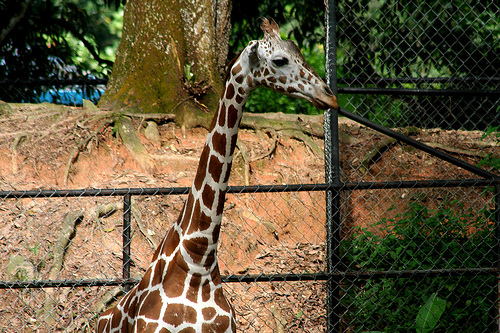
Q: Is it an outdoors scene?
A: Yes, it is outdoors.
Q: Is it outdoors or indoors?
A: It is outdoors.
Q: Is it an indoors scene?
A: No, it is outdoors.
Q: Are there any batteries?
A: No, there are no batteries.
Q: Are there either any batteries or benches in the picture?
A: No, there are no batteries or benches.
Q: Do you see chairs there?
A: No, there are no chairs.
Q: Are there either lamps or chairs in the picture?
A: No, there are no chairs or lamps.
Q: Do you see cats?
A: No, there are no cats.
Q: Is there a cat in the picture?
A: No, there are no cats.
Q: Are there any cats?
A: No, there are no cats.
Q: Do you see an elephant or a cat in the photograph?
A: No, there are no cats or elephants.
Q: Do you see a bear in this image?
A: No, there are no bears.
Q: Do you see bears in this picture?
A: No, there are no bears.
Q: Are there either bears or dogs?
A: No, there are no bears or dogs.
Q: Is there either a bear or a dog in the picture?
A: No, there are no bears or dogs.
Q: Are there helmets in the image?
A: No, there are no helmets.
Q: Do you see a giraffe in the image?
A: Yes, there is a giraffe.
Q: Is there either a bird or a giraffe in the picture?
A: Yes, there is a giraffe.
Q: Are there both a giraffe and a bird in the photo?
A: No, there is a giraffe but no birds.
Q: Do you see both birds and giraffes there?
A: No, there is a giraffe but no birds.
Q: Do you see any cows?
A: No, there are no cows.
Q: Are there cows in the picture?
A: No, there are no cows.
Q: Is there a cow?
A: No, there are no cows.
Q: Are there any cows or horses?
A: No, there are no cows or horses.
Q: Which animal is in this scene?
A: The animal is a giraffe.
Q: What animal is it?
A: The animal is a giraffe.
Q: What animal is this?
A: This is a giraffe.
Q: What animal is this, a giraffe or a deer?
A: This is a giraffe.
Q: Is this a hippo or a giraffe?
A: This is a giraffe.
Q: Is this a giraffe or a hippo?
A: This is a giraffe.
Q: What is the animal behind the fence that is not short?
A: The animal is a giraffe.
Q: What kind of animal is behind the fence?
A: The animal is a giraffe.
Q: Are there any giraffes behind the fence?
A: Yes, there is a giraffe behind the fence.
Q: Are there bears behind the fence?
A: No, there is a giraffe behind the fence.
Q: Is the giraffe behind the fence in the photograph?
A: Yes, the giraffe is behind the fence.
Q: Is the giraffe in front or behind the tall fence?
A: The giraffe is behind the fence.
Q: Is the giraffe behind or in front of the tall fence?
A: The giraffe is behind the fence.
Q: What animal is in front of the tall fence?
A: The giraffe is in front of the fence.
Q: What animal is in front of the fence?
A: The giraffe is in front of the fence.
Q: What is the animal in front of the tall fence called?
A: The animal is a giraffe.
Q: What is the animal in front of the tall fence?
A: The animal is a giraffe.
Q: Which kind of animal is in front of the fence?
A: The animal is a giraffe.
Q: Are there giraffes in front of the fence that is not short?
A: Yes, there is a giraffe in front of the fence.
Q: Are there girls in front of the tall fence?
A: No, there is a giraffe in front of the fence.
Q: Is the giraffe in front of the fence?
A: Yes, the giraffe is in front of the fence.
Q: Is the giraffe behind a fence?
A: No, the giraffe is in front of a fence.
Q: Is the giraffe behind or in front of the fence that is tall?
A: The giraffe is in front of the fence.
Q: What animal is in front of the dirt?
A: The giraffe is in front of the dirt.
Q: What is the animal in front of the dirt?
A: The animal is a giraffe.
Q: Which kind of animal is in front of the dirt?
A: The animal is a giraffe.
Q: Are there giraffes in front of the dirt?
A: Yes, there is a giraffe in front of the dirt.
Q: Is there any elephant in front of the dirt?
A: No, there is a giraffe in front of the dirt.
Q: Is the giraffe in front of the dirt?
A: Yes, the giraffe is in front of the dirt.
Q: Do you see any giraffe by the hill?
A: Yes, there is a giraffe by the hill.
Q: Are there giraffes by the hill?
A: Yes, there is a giraffe by the hill.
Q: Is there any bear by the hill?
A: No, there is a giraffe by the hill.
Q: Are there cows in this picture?
A: No, there are no cows.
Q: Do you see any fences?
A: Yes, there is a fence.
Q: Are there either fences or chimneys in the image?
A: Yes, there is a fence.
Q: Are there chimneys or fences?
A: Yes, there is a fence.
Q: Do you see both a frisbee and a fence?
A: No, there is a fence but no frisbees.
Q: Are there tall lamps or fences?
A: Yes, there is a tall fence.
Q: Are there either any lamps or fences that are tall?
A: Yes, the fence is tall.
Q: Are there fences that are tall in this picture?
A: Yes, there is a tall fence.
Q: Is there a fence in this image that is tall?
A: Yes, there is a fence that is tall.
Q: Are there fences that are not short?
A: Yes, there is a tall fence.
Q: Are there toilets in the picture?
A: No, there are no toilets.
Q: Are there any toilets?
A: No, there are no toilets.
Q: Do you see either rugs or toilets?
A: No, there are no toilets or rugs.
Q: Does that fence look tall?
A: Yes, the fence is tall.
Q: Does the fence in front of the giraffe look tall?
A: Yes, the fence is tall.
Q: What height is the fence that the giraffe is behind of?
A: The fence is tall.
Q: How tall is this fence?
A: The fence is tall.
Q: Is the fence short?
A: No, the fence is tall.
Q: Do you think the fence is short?
A: No, the fence is tall.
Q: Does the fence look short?
A: No, the fence is tall.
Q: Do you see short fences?
A: No, there is a fence but it is tall.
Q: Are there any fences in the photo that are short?
A: No, there is a fence but it is tall.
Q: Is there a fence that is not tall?
A: No, there is a fence but it is tall.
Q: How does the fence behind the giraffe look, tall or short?
A: The fence is tall.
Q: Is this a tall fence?
A: Yes, this is a tall fence.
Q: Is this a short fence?
A: No, this is a tall fence.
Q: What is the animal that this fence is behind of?
A: The animal is a giraffe.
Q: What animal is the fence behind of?
A: The fence is behind the giraffe.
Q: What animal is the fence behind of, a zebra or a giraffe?
A: The fence is behind a giraffe.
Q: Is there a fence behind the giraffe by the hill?
A: Yes, there is a fence behind the giraffe.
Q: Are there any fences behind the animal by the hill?
A: Yes, there is a fence behind the giraffe.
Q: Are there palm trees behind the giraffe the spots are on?
A: No, there is a fence behind the giraffe.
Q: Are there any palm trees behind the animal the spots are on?
A: No, there is a fence behind the giraffe.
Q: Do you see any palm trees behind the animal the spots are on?
A: No, there is a fence behind the giraffe.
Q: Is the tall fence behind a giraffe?
A: Yes, the fence is behind a giraffe.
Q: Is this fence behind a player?
A: No, the fence is behind a giraffe.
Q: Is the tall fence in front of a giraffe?
A: No, the fence is behind a giraffe.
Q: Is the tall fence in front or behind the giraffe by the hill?
A: The fence is behind the giraffe.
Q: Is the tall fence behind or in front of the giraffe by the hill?
A: The fence is behind the giraffe.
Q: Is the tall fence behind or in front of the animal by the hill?
A: The fence is behind the giraffe.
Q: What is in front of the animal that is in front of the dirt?
A: The fence is in front of the giraffe.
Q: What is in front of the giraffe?
A: The fence is in front of the giraffe.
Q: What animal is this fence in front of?
A: The fence is in front of the giraffe.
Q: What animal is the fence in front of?
A: The fence is in front of the giraffe.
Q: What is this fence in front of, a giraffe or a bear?
A: The fence is in front of a giraffe.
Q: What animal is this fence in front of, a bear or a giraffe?
A: The fence is in front of a giraffe.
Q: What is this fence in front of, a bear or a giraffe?
A: The fence is in front of a giraffe.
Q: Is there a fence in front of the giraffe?
A: Yes, there is a fence in front of the giraffe.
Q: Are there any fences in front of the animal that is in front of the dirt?
A: Yes, there is a fence in front of the giraffe.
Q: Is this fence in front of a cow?
A: No, the fence is in front of a giraffe.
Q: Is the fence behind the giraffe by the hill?
A: No, the fence is in front of the giraffe.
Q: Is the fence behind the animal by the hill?
A: No, the fence is in front of the giraffe.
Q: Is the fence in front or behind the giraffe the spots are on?
A: The fence is in front of the giraffe.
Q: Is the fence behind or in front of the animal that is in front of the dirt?
A: The fence is in front of the giraffe.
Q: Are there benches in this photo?
A: No, there are no benches.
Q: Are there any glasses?
A: No, there are no glasses.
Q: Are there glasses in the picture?
A: No, there are no glasses.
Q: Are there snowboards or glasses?
A: No, there are no glasses or snowboards.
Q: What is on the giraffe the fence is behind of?
A: The spots are on the giraffe.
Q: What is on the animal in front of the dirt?
A: The spots are on the giraffe.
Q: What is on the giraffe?
A: The spots are on the giraffe.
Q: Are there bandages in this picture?
A: No, there are no bandages.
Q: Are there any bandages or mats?
A: No, there are no bandages or mats.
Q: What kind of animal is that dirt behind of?
A: The dirt is behind the giraffe.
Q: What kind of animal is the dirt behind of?
A: The dirt is behind the giraffe.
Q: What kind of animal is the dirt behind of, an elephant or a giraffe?
A: The dirt is behind a giraffe.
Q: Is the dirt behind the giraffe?
A: Yes, the dirt is behind the giraffe.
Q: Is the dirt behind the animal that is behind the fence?
A: Yes, the dirt is behind the giraffe.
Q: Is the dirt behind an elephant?
A: No, the dirt is behind the giraffe.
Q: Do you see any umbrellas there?
A: No, there are no umbrellas.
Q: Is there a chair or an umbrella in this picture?
A: No, there are no umbrellas or chairs.